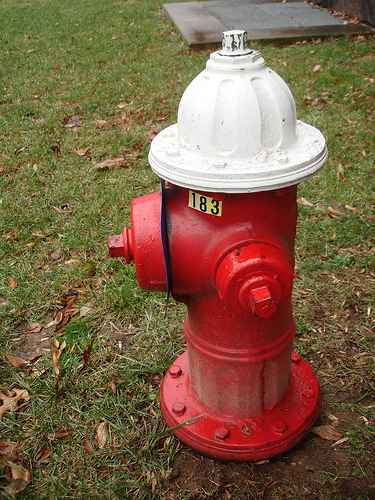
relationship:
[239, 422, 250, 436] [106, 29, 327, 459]
chip in paint of fire hydrant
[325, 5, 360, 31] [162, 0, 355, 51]
leaves laying on slab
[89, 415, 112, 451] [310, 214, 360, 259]
leaves in grass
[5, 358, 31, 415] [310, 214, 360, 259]
leaves in grass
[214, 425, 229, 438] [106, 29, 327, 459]
red bolt on fire hydrant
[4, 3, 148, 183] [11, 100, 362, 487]
grass on ground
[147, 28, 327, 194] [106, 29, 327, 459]
top of fire hydrant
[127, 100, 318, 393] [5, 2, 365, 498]
fire hydrant in area